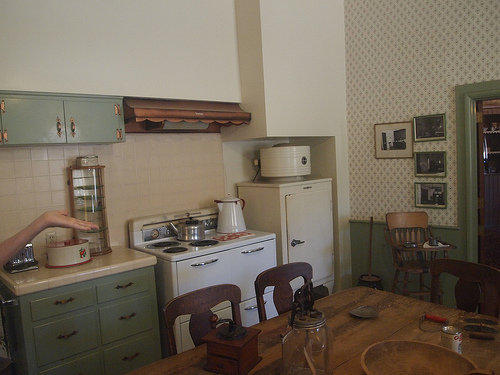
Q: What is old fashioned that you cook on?
A: Stove.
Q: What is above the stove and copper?
A: Exhaust fan.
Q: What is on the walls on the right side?
A: Wallpaper.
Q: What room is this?
A: Kitchen.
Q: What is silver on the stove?
A: Tea kettle.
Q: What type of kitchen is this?
A: Old fashioned.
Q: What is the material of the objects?
A: The chairs are wooden.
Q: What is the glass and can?
A: Stuff on the table.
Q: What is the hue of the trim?
A: The door frame is green.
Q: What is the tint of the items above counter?
A: The cabinets are green.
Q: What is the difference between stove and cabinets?
A: The oven is white.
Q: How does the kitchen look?
A: Clean.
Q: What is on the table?
A: Dishes.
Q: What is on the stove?
A: A tea kettle.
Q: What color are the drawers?
A: Teal.